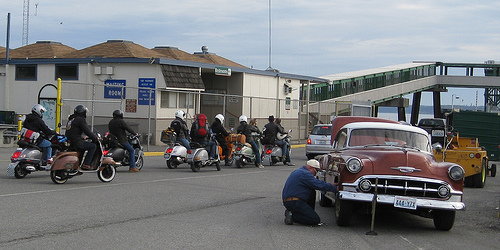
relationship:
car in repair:
[308, 76, 495, 221] [267, 138, 387, 221]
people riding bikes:
[16, 90, 303, 170] [23, 123, 305, 186]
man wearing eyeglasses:
[288, 155, 333, 181] [307, 165, 324, 176]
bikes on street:
[23, 123, 305, 186] [67, 158, 269, 239]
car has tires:
[308, 76, 495, 221] [322, 186, 362, 228]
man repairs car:
[288, 155, 333, 181] [308, 76, 495, 221]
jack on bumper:
[337, 167, 391, 245] [289, 0, 451, 229]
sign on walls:
[85, 67, 183, 118] [77, 66, 249, 155]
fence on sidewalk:
[16, 90, 303, 170] [53, 91, 288, 215]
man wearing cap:
[288, 155, 333, 181] [299, 143, 342, 185]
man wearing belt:
[288, 155, 333, 181] [279, 192, 304, 210]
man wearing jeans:
[288, 155, 333, 181] [259, 179, 339, 244]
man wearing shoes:
[288, 155, 333, 181] [123, 162, 171, 188]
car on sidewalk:
[308, 76, 495, 221] [53, 91, 288, 215]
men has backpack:
[162, 100, 278, 155] [153, 101, 227, 157]